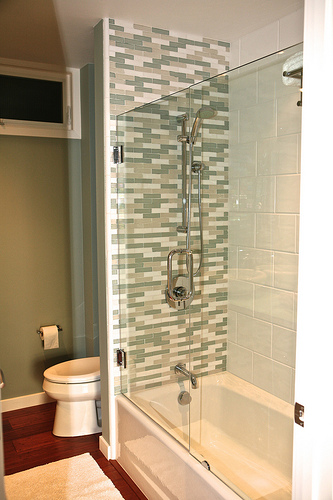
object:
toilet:
[42, 356, 102, 438]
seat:
[43, 357, 102, 385]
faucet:
[173, 362, 198, 392]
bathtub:
[118, 369, 293, 499]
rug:
[2, 452, 124, 500]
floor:
[1, 401, 147, 499]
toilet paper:
[40, 325, 61, 351]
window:
[1, 57, 84, 141]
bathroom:
[2, 1, 304, 500]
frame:
[1, 57, 83, 141]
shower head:
[195, 105, 219, 122]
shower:
[107, 18, 303, 499]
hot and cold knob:
[173, 286, 195, 302]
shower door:
[116, 42, 303, 499]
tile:
[104, 18, 231, 392]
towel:
[281, 51, 303, 85]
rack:
[281, 66, 304, 108]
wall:
[91, 18, 226, 394]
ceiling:
[2, 2, 305, 66]